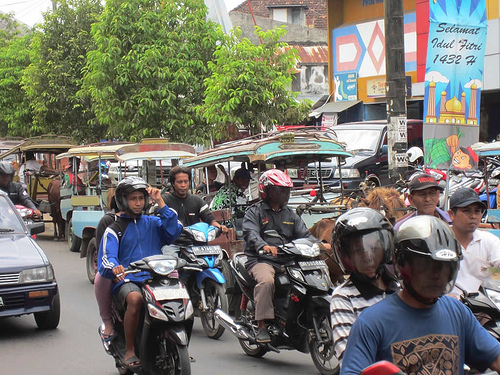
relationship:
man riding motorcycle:
[241, 166, 330, 254] [215, 236, 334, 372]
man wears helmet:
[241, 166, 330, 254] [256, 168, 294, 209]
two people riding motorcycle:
[94, 177, 180, 375] [131, 251, 197, 372]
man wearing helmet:
[241, 166, 330, 254] [256, 168, 294, 209]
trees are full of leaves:
[1, 0, 310, 138] [224, 97, 243, 112]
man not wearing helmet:
[161, 165, 213, 223] [256, 168, 294, 209]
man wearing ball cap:
[445, 190, 499, 302] [449, 189, 487, 209]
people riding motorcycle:
[1, 158, 499, 374] [213, 229, 341, 374]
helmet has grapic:
[256, 168, 294, 209] [257, 168, 294, 199]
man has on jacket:
[97, 176, 197, 367] [102, 209, 182, 280]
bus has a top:
[176, 126, 350, 212] [180, 126, 353, 168]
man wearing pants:
[241, 166, 330, 254] [247, 260, 277, 322]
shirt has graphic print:
[344, 297, 499, 374] [391, 335, 458, 373]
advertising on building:
[332, 74, 357, 102] [327, 3, 499, 144]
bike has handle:
[362, 360, 410, 374] [360, 361, 398, 373]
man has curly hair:
[161, 165, 213, 223] [168, 165, 192, 182]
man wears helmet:
[113, 182, 172, 248] [116, 176, 150, 212]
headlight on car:
[23, 266, 48, 285] [0, 192, 60, 327]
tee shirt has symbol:
[344, 297, 499, 374] [391, 335, 458, 373]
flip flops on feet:
[116, 351, 143, 370] [120, 347, 141, 371]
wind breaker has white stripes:
[102, 209, 182, 280] [102, 227, 114, 274]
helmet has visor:
[331, 207, 394, 280] [343, 230, 393, 279]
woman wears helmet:
[328, 207, 393, 360] [331, 207, 394, 280]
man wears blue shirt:
[341, 218, 499, 373] [344, 297, 499, 374]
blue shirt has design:
[344, 297, 499, 374] [391, 335, 458, 373]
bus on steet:
[176, 126, 350, 212] [0, 119, 500, 375]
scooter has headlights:
[184, 219, 229, 337] [192, 228, 215, 244]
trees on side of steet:
[1, 0, 310, 138] [0, 119, 500, 375]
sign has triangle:
[327, 18, 416, 88] [367, 21, 384, 50]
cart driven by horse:
[13, 136, 80, 230] [47, 175, 71, 242]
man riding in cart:
[20, 152, 54, 193] [13, 136, 80, 230]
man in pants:
[241, 166, 330, 254] [247, 260, 277, 322]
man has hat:
[445, 190, 499, 302] [449, 189, 487, 209]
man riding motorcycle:
[113, 182, 172, 248] [131, 251, 197, 372]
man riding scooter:
[161, 165, 213, 223] [174, 222, 231, 339]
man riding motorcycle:
[241, 166, 330, 254] [274, 235, 334, 369]